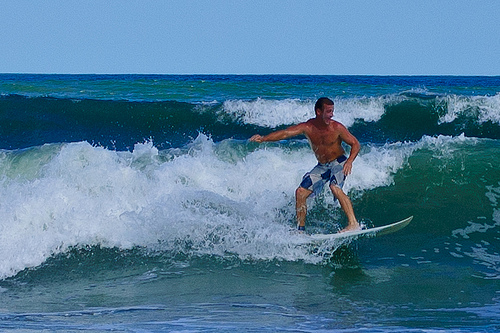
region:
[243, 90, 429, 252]
The man is on a surfboard.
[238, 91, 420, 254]
The surfboard is in the water.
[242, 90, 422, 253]
The man is wet.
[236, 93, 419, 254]
The surfboard is wet.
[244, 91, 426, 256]
The surfboard is white.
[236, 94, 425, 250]
Man's right arm is outstretched.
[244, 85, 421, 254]
The man is wearing shorts.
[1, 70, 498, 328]
The water is splashing.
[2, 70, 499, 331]
The water is wavy.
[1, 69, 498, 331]
The water is zealous.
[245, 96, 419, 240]
A man on a surfboard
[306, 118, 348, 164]
A man with no shirt on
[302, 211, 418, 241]
A man on a white surfboard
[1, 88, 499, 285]
Two waves breaking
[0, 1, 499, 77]
A bright blue sky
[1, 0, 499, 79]
A sky with no clouds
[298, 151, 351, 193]
White and blue diamond pattered shorts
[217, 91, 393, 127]
White crest of a wave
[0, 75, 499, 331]
Blue and green colored water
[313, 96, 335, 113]
A man with short brown hair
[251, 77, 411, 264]
man in ocean surfing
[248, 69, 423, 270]
man on white surfboard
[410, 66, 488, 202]
two large waves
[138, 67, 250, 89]
calm ocean water behind waves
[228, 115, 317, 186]
man's arm out to side for balance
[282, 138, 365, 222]
man wearing blue swim trunks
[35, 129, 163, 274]
white foam of crashing waves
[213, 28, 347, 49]
light blue sky with no clouds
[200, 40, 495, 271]
only one man surfing in ocean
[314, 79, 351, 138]
man with short brown hair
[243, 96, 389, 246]
man surfing on board in ocean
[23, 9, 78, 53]
white clouds in blue sky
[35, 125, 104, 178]
white clouds in blue sky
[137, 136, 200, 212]
white clouds in blue sky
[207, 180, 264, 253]
white clouds in blue sky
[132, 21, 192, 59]
white clouds in blue sky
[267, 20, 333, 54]
white clouds in blue sky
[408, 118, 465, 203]
white clouds in blue sky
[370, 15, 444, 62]
white clouds in blue sky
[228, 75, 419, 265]
a man on a surfboard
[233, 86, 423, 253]
a man in the ocean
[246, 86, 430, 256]
a man at the beach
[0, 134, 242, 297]
a breaking ocean wave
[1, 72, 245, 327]
beautiful blue ocean water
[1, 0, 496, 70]
a clear blue sky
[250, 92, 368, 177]
a man not wearing a shirt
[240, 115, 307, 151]
the arm of a man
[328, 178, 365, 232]
the left leg of a man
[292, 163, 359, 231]
the legs of a man